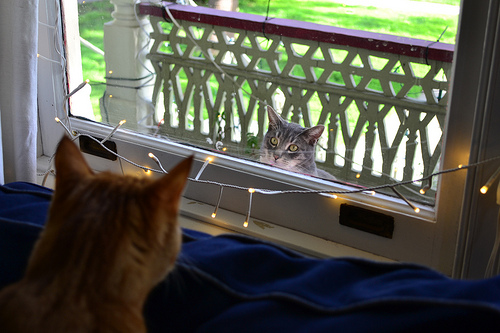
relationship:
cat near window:
[254, 104, 329, 178] [29, 2, 500, 279]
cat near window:
[3, 128, 197, 332] [29, 2, 500, 279]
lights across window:
[45, 83, 494, 212] [29, 2, 500, 279]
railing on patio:
[102, 5, 461, 197] [46, 3, 495, 211]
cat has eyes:
[254, 104, 329, 178] [267, 131, 303, 154]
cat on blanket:
[3, 128, 197, 332] [3, 184, 497, 332]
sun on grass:
[307, 2, 466, 21] [231, 2, 461, 45]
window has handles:
[29, 2, 500, 279] [80, 137, 398, 240]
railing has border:
[102, 5, 461, 197] [163, 8, 458, 60]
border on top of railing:
[163, 8, 458, 60] [102, 5, 461, 197]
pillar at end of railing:
[101, 2, 161, 132] [102, 5, 461, 197]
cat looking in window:
[254, 104, 329, 178] [29, 2, 500, 279]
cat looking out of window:
[3, 128, 197, 332] [29, 2, 500, 279]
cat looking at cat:
[254, 104, 329, 178] [3, 128, 197, 332]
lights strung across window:
[45, 83, 494, 212] [29, 2, 500, 279]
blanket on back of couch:
[3, 184, 497, 332] [3, 179, 498, 325]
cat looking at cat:
[3, 128, 197, 332] [254, 104, 329, 178]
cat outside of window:
[254, 104, 329, 178] [29, 2, 500, 279]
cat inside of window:
[3, 128, 197, 332] [29, 2, 500, 279]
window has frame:
[29, 2, 500, 279] [38, 7, 477, 244]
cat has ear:
[254, 104, 329, 178] [304, 123, 328, 146]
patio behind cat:
[46, 3, 495, 211] [254, 104, 329, 178]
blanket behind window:
[3, 184, 497, 332] [29, 2, 500, 279]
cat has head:
[3, 128, 197, 332] [42, 135, 195, 295]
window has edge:
[29, 2, 500, 279] [30, 152, 445, 274]